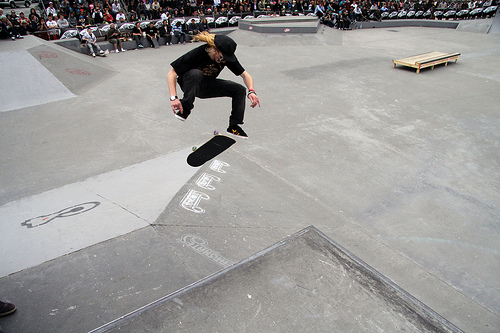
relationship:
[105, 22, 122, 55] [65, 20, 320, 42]
person sitting on bench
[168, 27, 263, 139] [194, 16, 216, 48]
girl has hair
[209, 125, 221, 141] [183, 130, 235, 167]
wheels on skateboard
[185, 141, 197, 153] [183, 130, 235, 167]
wheels on skateboard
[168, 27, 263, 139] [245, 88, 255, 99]
girl wearing bracelets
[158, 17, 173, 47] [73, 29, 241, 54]
peron sitting on bench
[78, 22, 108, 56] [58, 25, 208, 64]
spectator sitting on bench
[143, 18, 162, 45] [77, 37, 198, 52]
person sitting on bench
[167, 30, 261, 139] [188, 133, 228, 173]
man above skateboard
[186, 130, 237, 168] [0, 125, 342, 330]
black skateboard above ground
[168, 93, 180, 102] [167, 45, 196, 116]
watch on arm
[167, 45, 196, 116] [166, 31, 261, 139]
arm of man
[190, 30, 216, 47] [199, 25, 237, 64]
hair on man's head